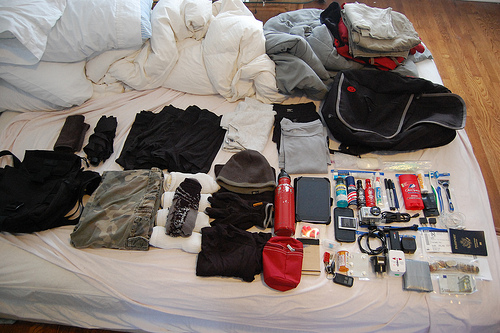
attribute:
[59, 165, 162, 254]
pattern — camo pattern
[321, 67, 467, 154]
backpack — black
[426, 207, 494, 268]
passport — black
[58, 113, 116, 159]
black sock — rolled up, gray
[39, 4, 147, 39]
pillows — White 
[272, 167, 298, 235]
bottle — red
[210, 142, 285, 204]
cap — skull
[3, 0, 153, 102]
pillows — stacked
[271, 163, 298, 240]
waterbottle — metal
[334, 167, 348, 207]
bottle — small, plastic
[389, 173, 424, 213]
deodorant — old spice